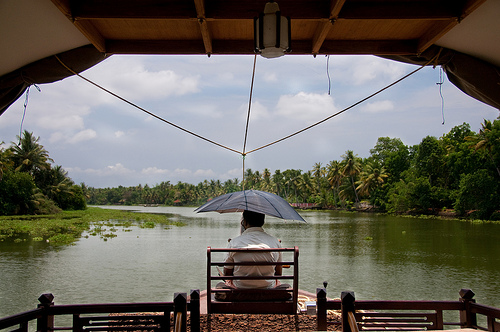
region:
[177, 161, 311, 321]
a man with umbrella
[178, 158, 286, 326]
a man with umbrella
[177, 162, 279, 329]
a man with umbrella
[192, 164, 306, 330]
a man with umbrella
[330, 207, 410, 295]
the water is green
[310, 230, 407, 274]
the water is green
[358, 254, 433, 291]
the water is green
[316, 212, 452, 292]
the water is green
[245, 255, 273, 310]
part of a chair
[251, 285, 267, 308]
part of a chaior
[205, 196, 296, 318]
this is a person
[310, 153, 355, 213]
this is a tree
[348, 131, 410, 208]
this is a tree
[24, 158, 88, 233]
this is a tree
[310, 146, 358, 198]
this is a tree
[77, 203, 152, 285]
the water is calm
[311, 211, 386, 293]
the water is calm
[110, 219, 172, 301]
the water is calm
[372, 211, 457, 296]
the water is calm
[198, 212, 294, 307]
this is a person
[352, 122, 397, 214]
this is a tree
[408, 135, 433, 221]
this is a tree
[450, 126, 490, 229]
this is a tree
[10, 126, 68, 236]
this is a tree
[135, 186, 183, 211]
this is a tree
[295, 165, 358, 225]
this is a tree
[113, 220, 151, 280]
the water is calm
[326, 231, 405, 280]
the water is calm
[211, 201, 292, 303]
this is a person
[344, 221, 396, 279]
the water is calm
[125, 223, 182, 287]
the water is calm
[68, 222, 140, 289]
the water is calm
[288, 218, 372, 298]
the water is calm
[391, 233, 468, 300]
the water is calm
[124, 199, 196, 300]
the water is calm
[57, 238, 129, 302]
the water is calm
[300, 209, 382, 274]
the water is calm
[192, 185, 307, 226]
black umbrella over the man's head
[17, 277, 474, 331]
brown railings around the seat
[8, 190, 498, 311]
green water in front of the man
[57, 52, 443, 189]
ropes above the man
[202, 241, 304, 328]
chair the man is sitting in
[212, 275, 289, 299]
cushion in the chair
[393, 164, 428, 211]
A tree in the woods.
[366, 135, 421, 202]
A tree in the woods.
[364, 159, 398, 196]
A tree in the woods.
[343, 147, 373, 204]
A tree in the woods.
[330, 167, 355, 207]
A tree in the woods.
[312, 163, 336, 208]
A tree in the woods.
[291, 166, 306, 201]
A tree in the woods.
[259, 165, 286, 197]
A tree in the woods.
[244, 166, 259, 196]
A tree in the woods.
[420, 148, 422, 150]
A green leaf on a plant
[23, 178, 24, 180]
A green leaf on a plant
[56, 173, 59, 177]
A green leaf on a plant